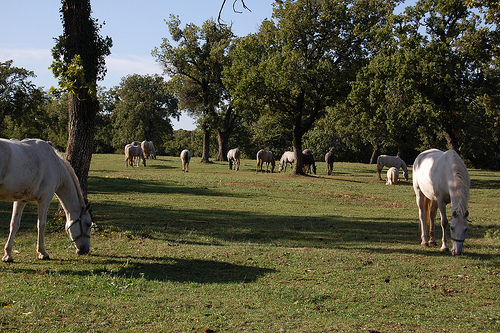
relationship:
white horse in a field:
[402, 148, 477, 253] [1, 154, 498, 331]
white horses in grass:
[4, 137, 483, 260] [1, 155, 496, 332]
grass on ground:
[1, 155, 496, 332] [1, 147, 497, 331]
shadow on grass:
[87, 238, 270, 293] [328, 262, 405, 324]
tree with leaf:
[223, 0, 394, 175] [308, 65, 323, 80]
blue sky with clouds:
[1, 0, 499, 131] [3, 44, 205, 126]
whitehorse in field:
[1, 125, 96, 265] [1, 154, 498, 331]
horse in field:
[177, 150, 187, 171] [1, 154, 498, 331]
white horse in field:
[410, 146, 470, 256] [1, 154, 498, 331]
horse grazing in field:
[123, 142, 148, 168] [1, 154, 498, 331]